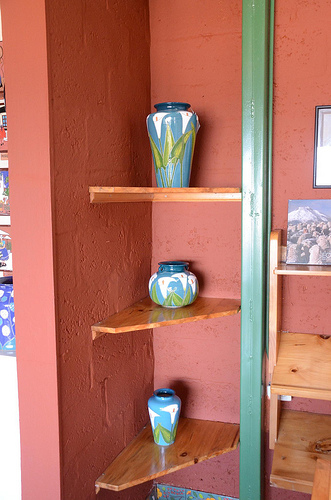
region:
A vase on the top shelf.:
[135, 99, 204, 190]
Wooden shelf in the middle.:
[90, 294, 245, 353]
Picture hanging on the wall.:
[303, 99, 329, 188]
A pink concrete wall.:
[25, 239, 85, 478]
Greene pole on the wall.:
[233, 9, 268, 487]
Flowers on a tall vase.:
[156, 123, 184, 182]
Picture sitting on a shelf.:
[283, 192, 329, 270]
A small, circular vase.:
[134, 249, 210, 316]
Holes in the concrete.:
[79, 236, 107, 266]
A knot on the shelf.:
[177, 448, 191, 459]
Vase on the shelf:
[147, 92, 196, 191]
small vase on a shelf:
[142, 385, 185, 447]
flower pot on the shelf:
[135, 247, 202, 305]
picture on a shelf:
[281, 193, 327, 273]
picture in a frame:
[307, 97, 328, 193]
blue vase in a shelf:
[143, 386, 185, 444]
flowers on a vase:
[150, 107, 194, 161]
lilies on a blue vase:
[151, 270, 193, 295]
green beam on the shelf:
[239, 7, 273, 299]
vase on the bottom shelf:
[141, 383, 178, 446]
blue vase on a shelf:
[138, 93, 202, 187]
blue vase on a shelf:
[138, 246, 197, 310]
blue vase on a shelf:
[133, 383, 187, 460]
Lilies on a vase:
[157, 404, 181, 429]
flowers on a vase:
[150, 269, 206, 288]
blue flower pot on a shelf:
[148, 255, 208, 314]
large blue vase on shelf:
[137, 99, 215, 184]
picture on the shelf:
[292, 196, 328, 248]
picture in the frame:
[302, 95, 329, 189]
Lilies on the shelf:
[142, 108, 199, 150]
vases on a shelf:
[74, 60, 244, 495]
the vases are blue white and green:
[140, 87, 202, 453]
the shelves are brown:
[71, 174, 247, 495]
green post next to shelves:
[226, 3, 284, 494]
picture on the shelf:
[280, 189, 329, 274]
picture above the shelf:
[296, 80, 328, 185]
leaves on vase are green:
[143, 126, 195, 169]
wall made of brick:
[0, 2, 329, 496]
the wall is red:
[1, 1, 328, 498]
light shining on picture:
[295, 134, 329, 186]